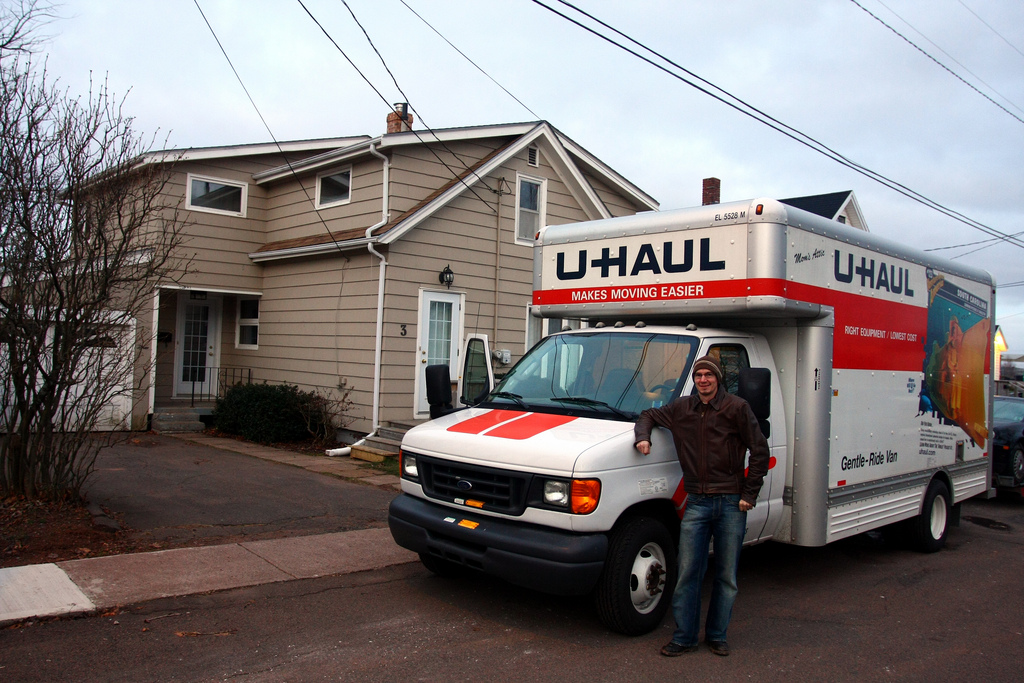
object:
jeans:
[670, 493, 750, 650]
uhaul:
[384, 188, 997, 637]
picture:
[914, 266, 988, 457]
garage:
[2, 303, 134, 501]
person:
[633, 355, 772, 659]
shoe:
[704, 639, 732, 657]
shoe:
[660, 641, 699, 657]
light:
[438, 263, 455, 289]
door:
[422, 291, 468, 415]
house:
[0, 102, 665, 468]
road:
[0, 493, 1022, 681]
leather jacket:
[633, 384, 770, 507]